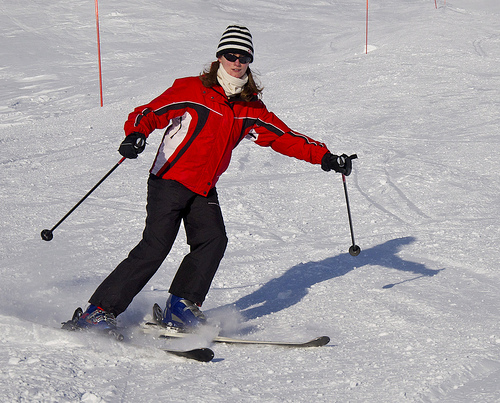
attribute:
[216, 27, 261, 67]
marvin — black, white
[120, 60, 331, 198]
jacket — red, black, white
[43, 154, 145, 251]
pole — black, red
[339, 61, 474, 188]
surface — sloppy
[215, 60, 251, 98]
cowl — white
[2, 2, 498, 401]
snow — white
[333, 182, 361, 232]
stick — thin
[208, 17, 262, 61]
hat — black, white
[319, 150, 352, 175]
gloves — black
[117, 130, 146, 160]
gloves — black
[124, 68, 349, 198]
jacket — red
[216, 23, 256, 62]
hat — striped, white, black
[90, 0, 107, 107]
pole — red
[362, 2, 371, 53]
pole — red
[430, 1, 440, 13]
pole — red